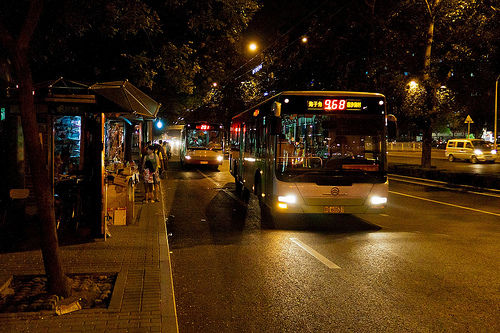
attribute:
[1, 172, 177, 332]
sidewalk — Tan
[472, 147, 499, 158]
headlights — on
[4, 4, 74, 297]
tree — brown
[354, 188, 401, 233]
lights — bright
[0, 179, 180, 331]
side walk — brick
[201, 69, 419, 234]
bus — green, white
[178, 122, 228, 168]
bus — driving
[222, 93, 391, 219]
bus — driving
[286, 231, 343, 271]
line — white